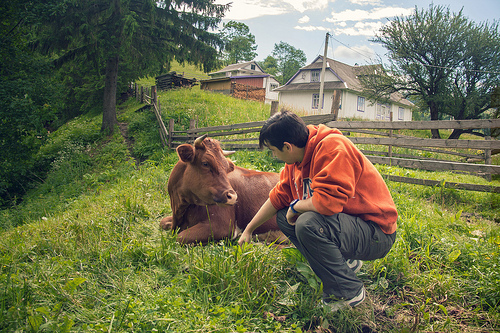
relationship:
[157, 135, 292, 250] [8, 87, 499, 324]
cow resting on ground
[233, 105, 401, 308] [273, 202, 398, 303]
man has pants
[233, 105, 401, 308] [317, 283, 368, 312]
man has shoe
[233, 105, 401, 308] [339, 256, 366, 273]
man has shoe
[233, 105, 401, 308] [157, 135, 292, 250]
man next to cow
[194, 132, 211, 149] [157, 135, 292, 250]
horn on cow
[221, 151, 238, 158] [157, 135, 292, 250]
horn on cow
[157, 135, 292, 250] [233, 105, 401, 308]
cow sitting next to man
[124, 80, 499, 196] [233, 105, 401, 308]
fence behind man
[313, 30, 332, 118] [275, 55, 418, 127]
utility pole in front of house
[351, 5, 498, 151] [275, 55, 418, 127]
tree to right of house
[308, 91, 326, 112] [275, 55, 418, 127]
window on house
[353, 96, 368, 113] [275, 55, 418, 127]
window on house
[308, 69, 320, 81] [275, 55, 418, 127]
window on house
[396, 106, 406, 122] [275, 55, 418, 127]
window on house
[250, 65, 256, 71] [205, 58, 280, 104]
window on house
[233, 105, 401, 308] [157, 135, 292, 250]
man with cow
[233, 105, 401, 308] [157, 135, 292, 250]
man looking at cow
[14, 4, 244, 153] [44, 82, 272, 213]
tree on hill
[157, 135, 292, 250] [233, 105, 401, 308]
cow looking at man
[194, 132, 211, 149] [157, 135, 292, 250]
horn of cow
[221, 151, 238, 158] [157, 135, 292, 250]
horn of cow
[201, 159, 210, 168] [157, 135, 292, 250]
eye of cow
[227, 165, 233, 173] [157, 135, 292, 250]
eye of cow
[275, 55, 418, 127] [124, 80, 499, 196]
house behind fence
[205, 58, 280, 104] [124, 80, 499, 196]
house behind fence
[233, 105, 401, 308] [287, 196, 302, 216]
man using watch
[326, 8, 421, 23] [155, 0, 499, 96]
cloud in sky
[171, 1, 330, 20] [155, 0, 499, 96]
cloud in sky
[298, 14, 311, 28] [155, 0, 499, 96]
cloud in sky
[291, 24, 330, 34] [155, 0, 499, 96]
cloud in sky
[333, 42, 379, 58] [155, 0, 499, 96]
cloud in sky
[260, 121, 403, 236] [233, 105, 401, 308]
sweatshirt on man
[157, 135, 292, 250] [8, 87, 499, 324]
cow laying on ground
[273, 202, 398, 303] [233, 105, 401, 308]
pants are on man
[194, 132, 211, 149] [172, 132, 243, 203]
horn on head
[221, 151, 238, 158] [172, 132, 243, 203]
horn on head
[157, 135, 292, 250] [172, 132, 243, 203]
cow has head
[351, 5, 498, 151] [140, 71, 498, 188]
tree in yard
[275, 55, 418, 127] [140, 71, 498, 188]
house in yard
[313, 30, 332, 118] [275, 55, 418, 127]
utility pole next to house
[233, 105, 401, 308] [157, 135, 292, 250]
man staring at cow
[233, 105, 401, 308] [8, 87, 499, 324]
man stooping on ground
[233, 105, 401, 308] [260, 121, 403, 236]
man wearing sweatshirt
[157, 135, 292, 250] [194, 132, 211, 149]
cow has horn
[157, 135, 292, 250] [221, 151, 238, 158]
cow has horn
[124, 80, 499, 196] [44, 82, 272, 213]
fence on hill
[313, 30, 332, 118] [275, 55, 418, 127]
utility pole near house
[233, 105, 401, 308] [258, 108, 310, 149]
man has hair